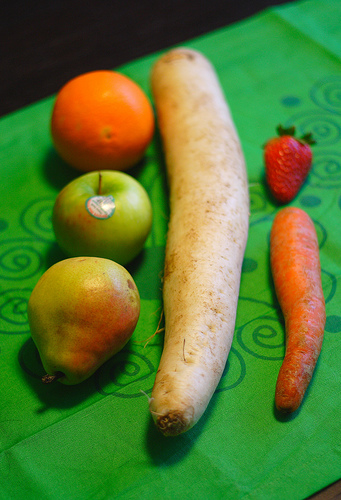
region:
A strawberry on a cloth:
[255, 125, 329, 202]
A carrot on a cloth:
[255, 195, 319, 429]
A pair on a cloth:
[18, 255, 135, 398]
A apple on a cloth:
[56, 162, 150, 256]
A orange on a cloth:
[43, 72, 155, 168]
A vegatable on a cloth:
[110, 175, 258, 437]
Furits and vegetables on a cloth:
[3, 65, 319, 444]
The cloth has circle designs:
[213, 315, 278, 436]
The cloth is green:
[43, 368, 124, 485]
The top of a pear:
[31, 351, 90, 402]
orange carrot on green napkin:
[274, 213, 327, 420]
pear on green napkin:
[39, 252, 126, 371]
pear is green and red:
[27, 256, 113, 369]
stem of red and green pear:
[40, 371, 79, 399]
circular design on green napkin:
[100, 353, 151, 405]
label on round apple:
[79, 197, 103, 217]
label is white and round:
[84, 196, 116, 218]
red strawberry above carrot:
[254, 120, 307, 205]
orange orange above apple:
[60, 88, 139, 159]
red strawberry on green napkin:
[263, 116, 328, 191]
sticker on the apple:
[85, 191, 117, 219]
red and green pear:
[26, 255, 140, 387]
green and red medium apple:
[50, 167, 152, 265]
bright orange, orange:
[50, 69, 154, 169]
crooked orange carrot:
[268, 207, 326, 414]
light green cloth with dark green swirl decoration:
[1, 0, 340, 499]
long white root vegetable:
[146, 47, 249, 437]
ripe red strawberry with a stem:
[259, 123, 317, 202]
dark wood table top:
[0, 0, 340, 499]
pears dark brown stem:
[39, 369, 64, 385]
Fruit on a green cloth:
[32, 83, 306, 350]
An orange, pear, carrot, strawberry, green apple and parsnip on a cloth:
[52, 89, 294, 301]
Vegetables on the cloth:
[175, 192, 321, 352]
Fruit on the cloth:
[31, 70, 131, 330]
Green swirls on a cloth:
[215, 303, 306, 367]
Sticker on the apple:
[78, 186, 125, 225]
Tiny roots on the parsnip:
[144, 299, 196, 378]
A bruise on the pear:
[115, 263, 143, 318]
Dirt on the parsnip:
[165, 233, 190, 280]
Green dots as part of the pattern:
[276, 85, 308, 116]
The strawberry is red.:
[258, 133, 316, 204]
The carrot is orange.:
[269, 209, 324, 415]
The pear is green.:
[20, 252, 133, 378]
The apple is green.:
[49, 159, 154, 259]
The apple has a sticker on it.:
[76, 191, 119, 217]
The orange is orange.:
[51, 66, 150, 167]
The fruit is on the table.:
[44, 67, 330, 420]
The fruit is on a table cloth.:
[2, 97, 332, 495]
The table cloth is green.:
[1, 101, 337, 493]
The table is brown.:
[5, 3, 174, 75]